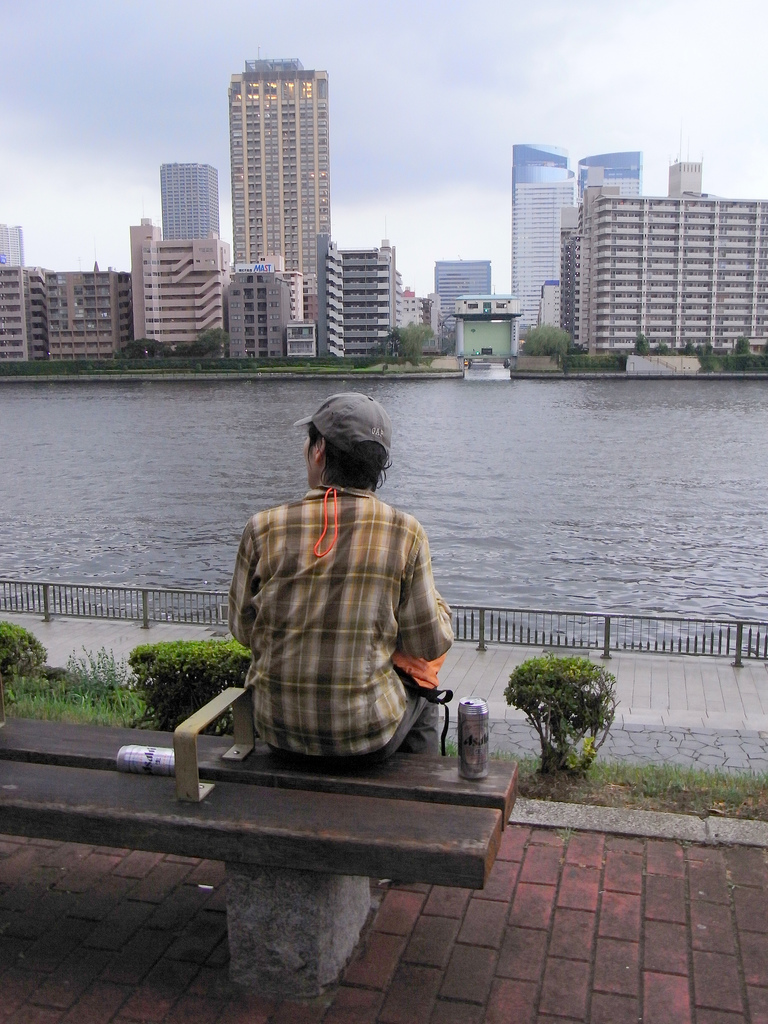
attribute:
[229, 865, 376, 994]
part — gray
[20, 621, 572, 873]
bench — wooden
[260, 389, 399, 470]
cap — grey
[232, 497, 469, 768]
shirt — brown plaid shirt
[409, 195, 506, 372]
brick pavers — red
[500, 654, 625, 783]
bush — small , green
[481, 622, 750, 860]
bush — small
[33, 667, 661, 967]
bench — wooden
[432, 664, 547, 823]
can — beverage can 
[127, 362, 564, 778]
man — sitting 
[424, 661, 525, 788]
can — lying on its side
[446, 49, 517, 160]
sky scraper — tallest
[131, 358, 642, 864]
man — sitting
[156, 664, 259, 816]
bar — metal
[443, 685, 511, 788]
cup — sitting